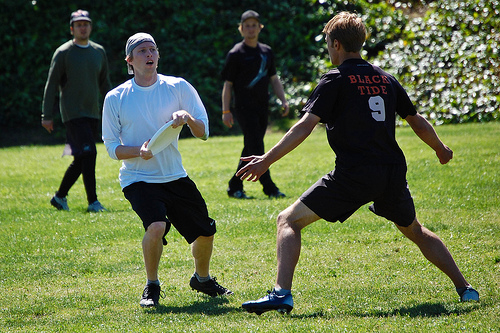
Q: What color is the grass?
A: Green.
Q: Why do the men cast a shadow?
A: It is sunny.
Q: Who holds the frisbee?
A: The man in the white shirt.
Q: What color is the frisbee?
A: White.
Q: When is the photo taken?
A: Daytime.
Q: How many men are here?
A: Four.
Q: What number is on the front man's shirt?
A: 9.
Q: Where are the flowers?
A: Behind the men.